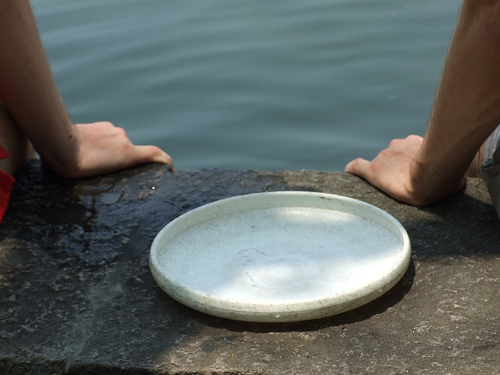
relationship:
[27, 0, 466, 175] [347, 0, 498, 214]
water before person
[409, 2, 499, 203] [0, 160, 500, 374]
arm on wall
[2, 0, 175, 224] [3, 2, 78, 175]
man resting arm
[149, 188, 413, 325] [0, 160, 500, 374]
frisbee on wall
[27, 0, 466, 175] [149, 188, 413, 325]
water before frisbee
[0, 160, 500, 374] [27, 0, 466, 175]
wall near water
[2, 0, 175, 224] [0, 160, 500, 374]
man sitting on wall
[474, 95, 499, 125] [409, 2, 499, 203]
vein on arm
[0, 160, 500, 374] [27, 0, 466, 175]
wall next to water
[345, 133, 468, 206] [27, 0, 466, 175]
hand near water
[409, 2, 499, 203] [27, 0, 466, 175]
arm near water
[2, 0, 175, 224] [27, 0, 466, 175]
man next to water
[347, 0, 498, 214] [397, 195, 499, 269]
person has shadow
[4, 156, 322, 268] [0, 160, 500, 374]
wet spot on wall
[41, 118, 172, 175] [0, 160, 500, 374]
hand on wall